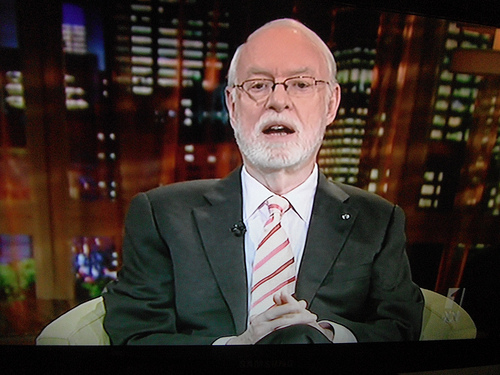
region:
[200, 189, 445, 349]
A man is visible.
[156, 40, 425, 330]
A man is visible.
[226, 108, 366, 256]
A man is visible.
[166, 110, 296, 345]
A man is visible.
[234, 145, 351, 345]
A man is visible.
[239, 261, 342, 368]
A man is visible.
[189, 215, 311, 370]
A man is visible.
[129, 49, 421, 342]
One man is speaking.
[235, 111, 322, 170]
Man has white beard.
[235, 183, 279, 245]
Man is wearing white colllar shirt.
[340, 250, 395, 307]
Man is wearing black coat.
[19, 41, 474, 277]
Poster behind the man.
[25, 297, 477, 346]
Man is sitting in chair.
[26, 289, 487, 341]
Chair is white color.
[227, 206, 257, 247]
Man has microphone attached to his coat.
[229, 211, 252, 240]
Microphone is black color.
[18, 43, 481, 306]
Poster is mainly brown color.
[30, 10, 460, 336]
man speaking while looking directly ahead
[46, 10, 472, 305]
speaker seated in front of city buildings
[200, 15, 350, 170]
man with grey hair, mustache and beard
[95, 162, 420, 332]
man wearing dark gray suit with tie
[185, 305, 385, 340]
hands folded on top of elevated knee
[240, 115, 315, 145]
mouth open revealing upper and lower teeth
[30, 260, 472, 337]
man seated in curved white seat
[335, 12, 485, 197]
lights shining from tall buildings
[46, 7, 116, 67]
deep blue sky in back of building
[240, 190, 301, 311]
white tie with red and pink slanted stripes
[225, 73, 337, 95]
the man's eyeglasses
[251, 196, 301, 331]
a white, pink and red tie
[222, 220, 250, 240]
a small microphone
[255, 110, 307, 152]
an open mouth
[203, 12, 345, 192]
the head of an older man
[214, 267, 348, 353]
a man with his hands together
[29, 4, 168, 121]
a building in the background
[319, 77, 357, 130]
the man's ear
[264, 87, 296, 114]
the man's white nose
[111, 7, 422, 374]
a man sitting in a tan chair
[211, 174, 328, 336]
The tie is striped.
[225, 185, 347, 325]
The tie is red and white.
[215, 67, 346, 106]
The man is wearing eyeglasses.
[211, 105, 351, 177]
The man has a beard.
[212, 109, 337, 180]
The beard is white.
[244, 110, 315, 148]
The man is speaking.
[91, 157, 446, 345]
The man wears a suit.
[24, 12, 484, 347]
The man sits in a chair.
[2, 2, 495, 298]
Skyscrapers are behind the man.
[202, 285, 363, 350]
The man's hands are together.